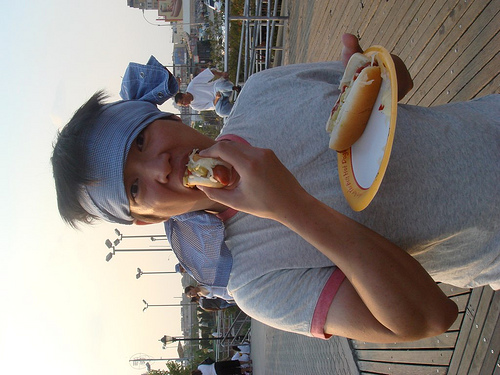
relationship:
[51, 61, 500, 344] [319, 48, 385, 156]
man eats hot dog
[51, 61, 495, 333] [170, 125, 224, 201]
man eats hot dog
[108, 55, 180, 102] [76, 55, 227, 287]
knot on bandana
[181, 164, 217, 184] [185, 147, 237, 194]
mustard on hot dog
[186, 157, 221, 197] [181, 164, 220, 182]
onions on hot dog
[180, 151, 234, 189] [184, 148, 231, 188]
hot dog on bun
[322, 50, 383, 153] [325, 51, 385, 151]
hot dog on bun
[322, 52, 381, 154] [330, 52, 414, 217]
hot dog on plate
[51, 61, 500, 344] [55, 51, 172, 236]
man wears bandana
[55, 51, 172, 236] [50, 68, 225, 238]
bandana on head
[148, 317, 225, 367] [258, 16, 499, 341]
lamp on deck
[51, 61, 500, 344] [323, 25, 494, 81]
man on decking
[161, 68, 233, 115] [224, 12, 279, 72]
man sits on fence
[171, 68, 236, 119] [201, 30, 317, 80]
man sits on sidewalk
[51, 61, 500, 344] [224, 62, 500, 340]
man wearing shirt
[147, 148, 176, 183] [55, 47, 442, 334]
nose on man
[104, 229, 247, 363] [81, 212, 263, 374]
lamp with lamp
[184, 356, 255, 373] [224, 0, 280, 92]
person standing near fence